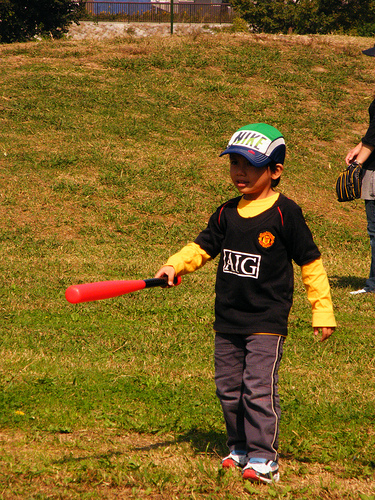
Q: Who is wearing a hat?
A: The boy.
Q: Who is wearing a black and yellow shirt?
A: The boy.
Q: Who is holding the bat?
A: The boy.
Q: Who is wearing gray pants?
A: The boy.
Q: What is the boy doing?
A: Playing baseball.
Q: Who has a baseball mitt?
A: The person standing behind the boy.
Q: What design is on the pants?
A: A stripe.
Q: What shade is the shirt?
A: Black.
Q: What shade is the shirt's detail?
A: Red.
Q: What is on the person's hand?
A: A mitt.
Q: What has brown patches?
A: The grass.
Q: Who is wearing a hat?
A: A boy.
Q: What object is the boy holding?
A: A bat.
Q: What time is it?
A: Afternoon.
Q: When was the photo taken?
A: During the daytime.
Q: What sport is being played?
A: Baseball.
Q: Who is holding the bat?
A: A boy.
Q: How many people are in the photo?
A: 2.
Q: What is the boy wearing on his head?
A: A hat.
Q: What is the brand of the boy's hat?
A: Nike.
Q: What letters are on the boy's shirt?
A: AIG.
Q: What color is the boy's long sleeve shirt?
A: Yellow.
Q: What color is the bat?
A: Red and black.